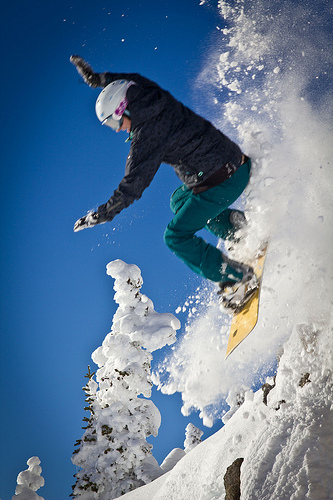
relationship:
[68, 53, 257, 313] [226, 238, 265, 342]
man riding snow board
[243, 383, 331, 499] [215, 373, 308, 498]
snow covering ground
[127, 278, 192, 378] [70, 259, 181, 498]
snow on tree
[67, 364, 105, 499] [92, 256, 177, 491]
pine tree covered in snow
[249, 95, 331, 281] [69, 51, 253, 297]
snow powder kicked up by snowboarderr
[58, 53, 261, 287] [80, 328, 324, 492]
man snowboarding down hill